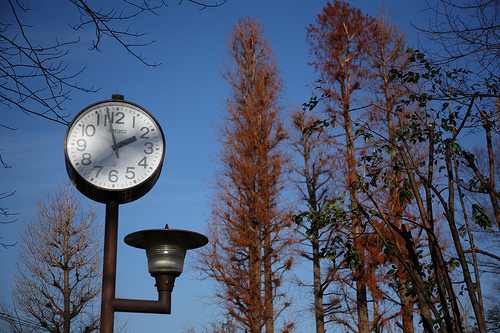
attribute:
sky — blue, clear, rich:
[0, 0, 499, 332]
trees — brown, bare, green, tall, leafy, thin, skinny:
[214, 1, 500, 332]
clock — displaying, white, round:
[55, 82, 231, 331]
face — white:
[68, 105, 161, 182]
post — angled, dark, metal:
[85, 200, 129, 327]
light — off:
[119, 222, 211, 316]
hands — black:
[105, 110, 140, 153]